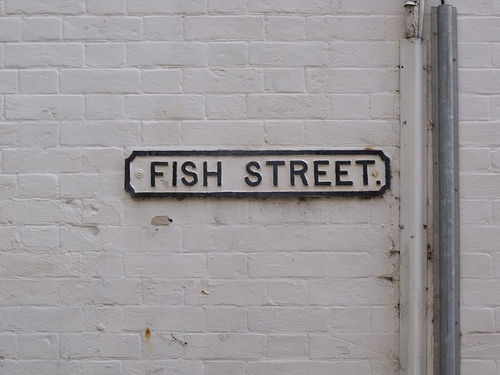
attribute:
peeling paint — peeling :
[145, 208, 176, 230]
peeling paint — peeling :
[71, 218, 103, 240]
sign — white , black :
[160, 145, 367, 216]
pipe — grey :
[433, 55, 459, 307]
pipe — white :
[399, 71, 430, 295]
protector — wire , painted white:
[397, 34, 429, 374]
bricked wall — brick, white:
[53, 222, 388, 372]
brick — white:
[19, 14, 66, 45]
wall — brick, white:
[143, 44, 275, 114]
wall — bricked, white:
[224, 46, 384, 111]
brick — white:
[265, 284, 347, 304]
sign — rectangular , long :
[66, 131, 401, 213]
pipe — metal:
[432, 1, 462, 371]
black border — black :
[121, 136, 390, 201]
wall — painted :
[234, 39, 375, 122]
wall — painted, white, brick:
[225, 47, 318, 92]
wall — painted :
[16, 20, 373, 141]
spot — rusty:
[135, 320, 159, 349]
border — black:
[122, 146, 393, 201]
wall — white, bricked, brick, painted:
[4, 6, 484, 361]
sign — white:
[115, 133, 394, 215]